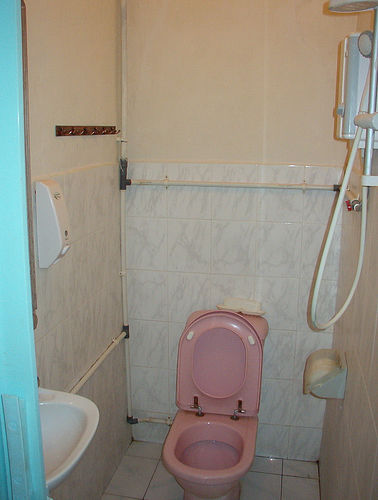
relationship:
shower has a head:
[305, 0, 378, 342] [355, 32, 375, 58]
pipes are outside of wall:
[64, 0, 352, 396] [21, 0, 377, 499]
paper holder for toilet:
[301, 349, 346, 401] [162, 311, 271, 499]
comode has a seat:
[162, 311, 271, 499] [176, 309, 262, 419]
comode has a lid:
[162, 311, 271, 499] [176, 309, 262, 419]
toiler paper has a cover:
[300, 348, 340, 395] [301, 349, 346, 401]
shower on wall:
[305, 0, 378, 342] [21, 0, 377, 499]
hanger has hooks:
[55, 125, 121, 137] [57, 127, 119, 135]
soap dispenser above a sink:
[35, 182, 73, 269] [38, 385, 104, 493]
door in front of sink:
[2, 0, 47, 500] [38, 385, 104, 493]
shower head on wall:
[355, 32, 375, 58] [21, 0, 377, 499]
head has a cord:
[355, 32, 375, 58] [305, 0, 378, 342]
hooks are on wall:
[57, 127, 119, 135] [21, 0, 377, 499]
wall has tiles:
[21, 0, 377, 499] [28, 160, 377, 499]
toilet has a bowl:
[162, 311, 271, 499] [159, 414, 258, 480]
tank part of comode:
[181, 311, 271, 347] [162, 311, 271, 499]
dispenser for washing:
[35, 182, 73, 269] [38, 385, 104, 493]